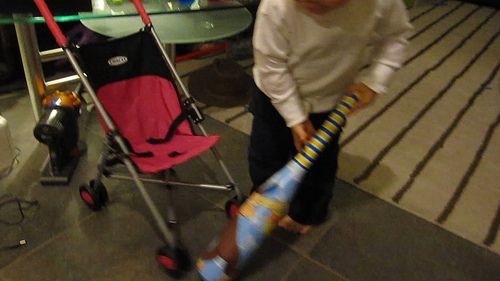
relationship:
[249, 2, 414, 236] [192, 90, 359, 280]
child holding bat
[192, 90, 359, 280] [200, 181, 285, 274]
bat has charactors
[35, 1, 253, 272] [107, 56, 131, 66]
stroller has logo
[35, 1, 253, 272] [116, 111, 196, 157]
stroller has strap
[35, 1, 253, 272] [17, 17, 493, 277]
stroller on floor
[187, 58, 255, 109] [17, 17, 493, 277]
hat on floor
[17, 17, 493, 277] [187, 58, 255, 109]
floor has hat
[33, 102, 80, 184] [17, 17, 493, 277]
fan on floor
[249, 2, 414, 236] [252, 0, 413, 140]
child wearing shirt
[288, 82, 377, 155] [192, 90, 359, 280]
hands holding bat